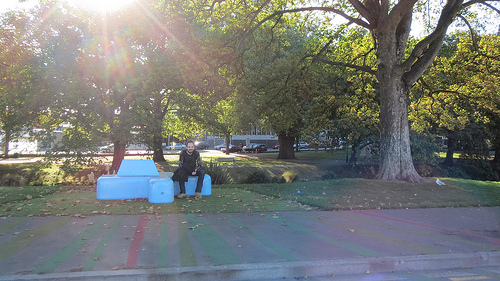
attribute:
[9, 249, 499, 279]
curb — concrete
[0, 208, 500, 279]
stripes — green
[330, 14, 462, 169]
tree — large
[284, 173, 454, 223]
leaves — dead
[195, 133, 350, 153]
cars — parked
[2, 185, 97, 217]
leaves — brown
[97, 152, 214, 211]
bench — blue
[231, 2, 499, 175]
tree — thick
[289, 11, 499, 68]
sky — gray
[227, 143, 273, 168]
car — parked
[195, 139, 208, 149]
car — parked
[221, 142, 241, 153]
car — parked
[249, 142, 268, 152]
car — parked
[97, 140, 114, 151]
car — parked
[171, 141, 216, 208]
person — sitting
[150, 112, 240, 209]
man — sitting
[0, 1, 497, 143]
leaves — green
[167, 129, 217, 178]
shirt — black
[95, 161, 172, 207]
bench — blue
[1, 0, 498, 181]
trees — green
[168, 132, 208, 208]
person — sitting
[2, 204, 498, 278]
sidewalk — colorful